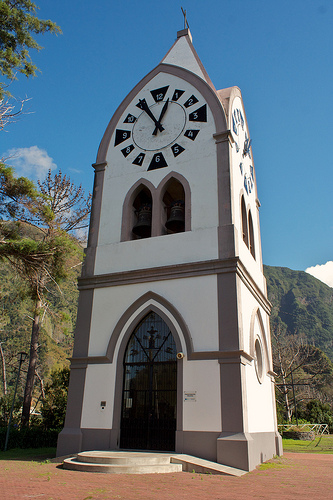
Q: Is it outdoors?
A: Yes, it is outdoors.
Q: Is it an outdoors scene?
A: Yes, it is outdoors.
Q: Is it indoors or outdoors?
A: It is outdoors.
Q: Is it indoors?
A: No, it is outdoors.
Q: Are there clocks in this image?
A: Yes, there is a clock.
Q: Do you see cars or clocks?
A: Yes, there is a clock.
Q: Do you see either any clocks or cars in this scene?
A: Yes, there is a clock.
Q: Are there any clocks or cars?
A: Yes, there is a clock.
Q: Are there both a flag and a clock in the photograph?
A: No, there is a clock but no flags.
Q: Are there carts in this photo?
A: No, there are no carts.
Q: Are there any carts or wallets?
A: No, there are no carts or wallets.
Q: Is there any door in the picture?
A: Yes, there is a door.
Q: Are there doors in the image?
A: Yes, there is a door.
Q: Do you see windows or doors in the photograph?
A: Yes, there is a door.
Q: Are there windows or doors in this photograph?
A: Yes, there is a door.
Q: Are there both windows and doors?
A: Yes, there are both a door and a window.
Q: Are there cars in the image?
A: No, there are no cars.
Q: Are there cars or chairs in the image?
A: No, there are no cars or chairs.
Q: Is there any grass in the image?
A: Yes, there is grass.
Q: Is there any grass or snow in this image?
A: Yes, there is grass.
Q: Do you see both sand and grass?
A: No, there is grass but no sand.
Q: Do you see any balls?
A: No, there are no balls.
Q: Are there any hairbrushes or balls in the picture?
A: No, there are no balls or hairbrushes.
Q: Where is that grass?
A: The grass is on the ground.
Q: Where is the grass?
A: The grass is on the ground.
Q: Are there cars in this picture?
A: No, there are no cars.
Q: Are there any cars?
A: No, there are no cars.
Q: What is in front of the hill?
A: The tower is in front of the hill.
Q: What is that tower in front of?
A: The tower is in front of the hill.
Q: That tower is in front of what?
A: The tower is in front of the hill.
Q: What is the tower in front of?
A: The tower is in front of the hill.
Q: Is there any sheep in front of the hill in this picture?
A: No, there is a tower in front of the hill.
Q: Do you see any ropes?
A: No, there are no ropes.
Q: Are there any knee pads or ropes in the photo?
A: No, there are no ropes or knee pads.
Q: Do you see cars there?
A: No, there are no cars.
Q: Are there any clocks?
A: Yes, there is a clock.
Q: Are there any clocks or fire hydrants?
A: Yes, there is a clock.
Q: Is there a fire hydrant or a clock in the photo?
A: Yes, there is a clock.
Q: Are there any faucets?
A: No, there are no faucets.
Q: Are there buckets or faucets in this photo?
A: No, there are no faucets or buckets.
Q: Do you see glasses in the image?
A: No, there are no glasses.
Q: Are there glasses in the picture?
A: No, there are no glasses.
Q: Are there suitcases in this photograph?
A: No, there are no suitcases.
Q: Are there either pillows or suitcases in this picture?
A: No, there are no suitcases or pillows.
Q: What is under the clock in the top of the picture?
A: The bell is under the clock.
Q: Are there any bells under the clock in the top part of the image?
A: Yes, there is a bell under the clock.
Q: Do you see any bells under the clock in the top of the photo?
A: Yes, there is a bell under the clock.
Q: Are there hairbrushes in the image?
A: No, there are no hairbrushes.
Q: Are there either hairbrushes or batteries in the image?
A: No, there are no hairbrushes or batteries.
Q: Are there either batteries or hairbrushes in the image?
A: No, there are no hairbrushes or batteries.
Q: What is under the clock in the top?
A: The bell is under the clock.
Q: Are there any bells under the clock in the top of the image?
A: Yes, there is a bell under the clock.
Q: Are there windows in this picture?
A: Yes, there is a window.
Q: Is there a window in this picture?
A: Yes, there is a window.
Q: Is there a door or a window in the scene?
A: Yes, there is a window.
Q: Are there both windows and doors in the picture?
A: Yes, there are both a window and a door.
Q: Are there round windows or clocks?
A: Yes, there is a round window.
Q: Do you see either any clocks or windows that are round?
A: Yes, the window is round.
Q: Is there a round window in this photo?
A: Yes, there is a round window.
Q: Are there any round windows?
A: Yes, there is a round window.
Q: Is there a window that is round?
A: Yes, there is a window that is round.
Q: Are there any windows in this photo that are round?
A: Yes, there is a window that is round.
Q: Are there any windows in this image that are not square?
A: Yes, there is a round window.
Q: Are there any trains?
A: No, there are no trains.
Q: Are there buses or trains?
A: No, there are no trains or buses.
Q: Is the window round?
A: Yes, the window is round.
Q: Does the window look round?
A: Yes, the window is round.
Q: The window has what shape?
A: The window is round.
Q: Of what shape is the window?
A: The window is round.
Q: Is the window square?
A: No, the window is round.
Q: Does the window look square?
A: No, the window is round.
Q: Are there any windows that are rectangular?
A: No, there is a window but it is round.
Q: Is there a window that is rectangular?
A: No, there is a window but it is round.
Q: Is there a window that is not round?
A: No, there is a window but it is round.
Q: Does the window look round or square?
A: The window is round.